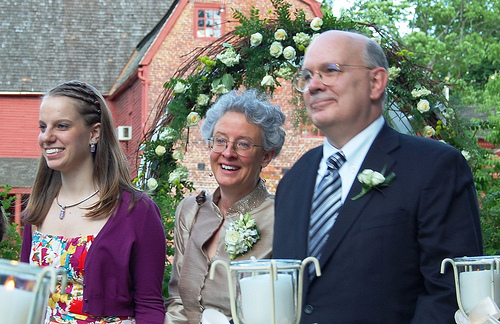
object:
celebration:
[25, 42, 472, 292]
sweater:
[14, 180, 169, 324]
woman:
[17, 80, 167, 322]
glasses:
[206, 135, 266, 157]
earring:
[90, 141, 96, 153]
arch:
[130, 12, 483, 194]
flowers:
[247, 31, 264, 48]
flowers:
[215, 47, 244, 69]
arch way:
[127, 0, 499, 297]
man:
[269, 28, 483, 324]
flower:
[349, 167, 394, 202]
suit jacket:
[269, 125, 485, 324]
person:
[161, 89, 286, 324]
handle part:
[267, 259, 279, 285]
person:
[18, 79, 168, 324]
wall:
[81, 46, 261, 156]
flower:
[269, 40, 281, 57]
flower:
[416, 97, 433, 114]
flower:
[283, 45, 297, 61]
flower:
[309, 17, 324, 32]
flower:
[186, 111, 202, 126]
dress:
[28, 223, 95, 322]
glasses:
[292, 63, 346, 93]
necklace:
[48, 184, 108, 221]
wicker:
[138, 13, 282, 172]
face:
[299, 32, 371, 126]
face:
[210, 110, 264, 186]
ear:
[89, 122, 103, 153]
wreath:
[145, 12, 435, 123]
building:
[0, 0, 353, 189]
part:
[271, 258, 278, 272]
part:
[363, 170, 372, 180]